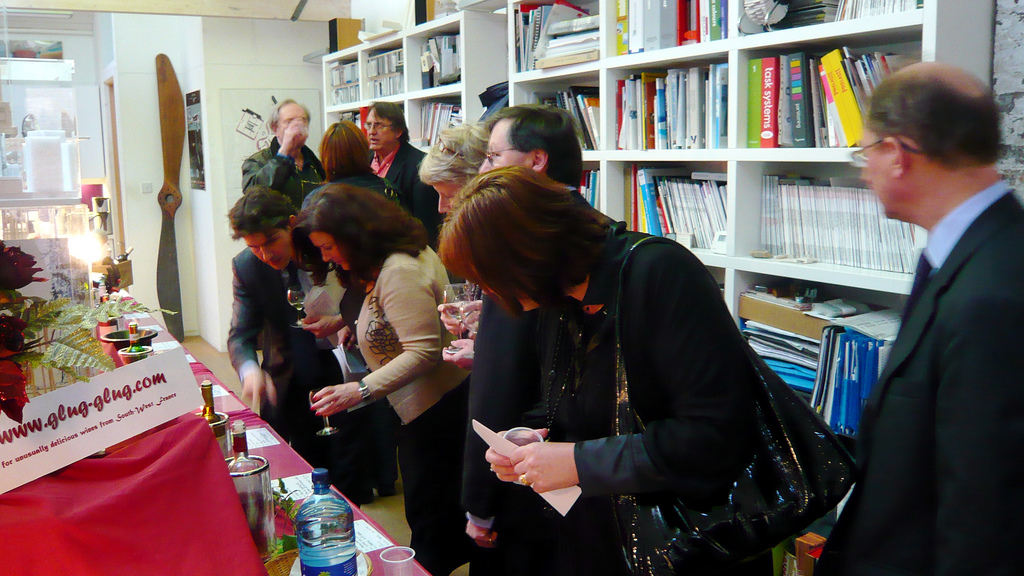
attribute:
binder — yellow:
[821, 54, 863, 144]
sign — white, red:
[47, 58, 330, 454]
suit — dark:
[814, 213, 1016, 572]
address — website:
[12, 369, 211, 476]